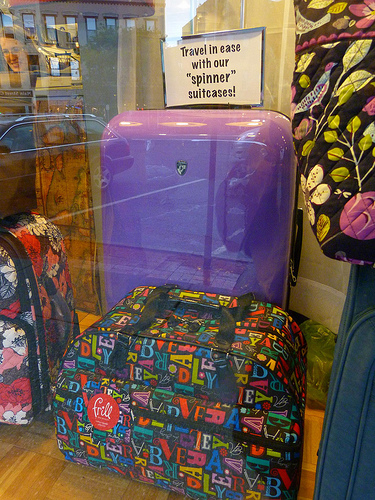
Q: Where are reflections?
A: On the window.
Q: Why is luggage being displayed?
A: To be sold.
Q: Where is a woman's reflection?
A: On the window.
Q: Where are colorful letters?
A: On a bag.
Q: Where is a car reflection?
A: On window.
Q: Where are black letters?
A: On white sign.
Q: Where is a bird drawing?
A: On bag on the right.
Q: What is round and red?
A: A sticker.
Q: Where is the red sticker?
A: On bag on the floor.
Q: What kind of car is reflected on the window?
A: A station wagon.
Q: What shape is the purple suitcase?
A: Rectangular.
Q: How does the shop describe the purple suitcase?
A: As a "spinner".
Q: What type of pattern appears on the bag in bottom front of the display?
A: Multi-colored letters.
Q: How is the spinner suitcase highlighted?
A: By a black and white sign hanging above it.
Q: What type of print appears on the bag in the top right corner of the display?
A: Birds, flowers and leaves.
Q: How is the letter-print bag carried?
A: Two black hand straps.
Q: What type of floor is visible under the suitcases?
A: Wood.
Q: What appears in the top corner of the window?
A: A woman's face reflected in the glass.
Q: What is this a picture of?
A: Suitcases.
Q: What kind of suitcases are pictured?
A: Spinner.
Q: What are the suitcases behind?
A: Glass.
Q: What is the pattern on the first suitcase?
A: Floral.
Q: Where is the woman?
A: Store.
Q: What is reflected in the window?
A: Car.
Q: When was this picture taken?
A: Daytime.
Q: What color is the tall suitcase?
A: Purple.